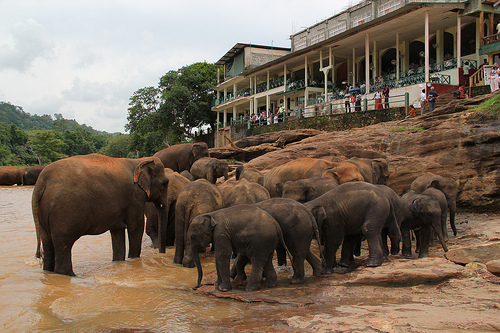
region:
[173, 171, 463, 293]
Group of baby elephants near the water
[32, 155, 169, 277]
Large elephant standing in the water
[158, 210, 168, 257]
Elephant's trunk partially submerged in water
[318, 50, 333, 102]
Y shaped column attached to roof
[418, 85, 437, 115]
People walking up the stairs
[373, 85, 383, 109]
Woman in red skirt and white top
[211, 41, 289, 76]
Flat roof on top of building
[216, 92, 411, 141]
Short metal railing above wall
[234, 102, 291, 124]
People in background watching elephants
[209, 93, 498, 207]
Steep jagged rocky background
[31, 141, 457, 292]
gathering of elephants by water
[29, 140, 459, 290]
elephants coming to bathe and drink water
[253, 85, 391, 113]
people observing elephants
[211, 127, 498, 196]
large rock wall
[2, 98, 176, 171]
lots of trees on mountain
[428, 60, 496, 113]
flight of stairs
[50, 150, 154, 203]
elephant covered in mud from bathing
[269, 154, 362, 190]
elephant coated skin in mud to stay cool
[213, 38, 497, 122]
three story building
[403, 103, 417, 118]
observer setting down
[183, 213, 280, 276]
Gray elephant standing on rock.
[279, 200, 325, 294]
Elephant standing on rock.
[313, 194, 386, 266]
Gray elephant standing on rock.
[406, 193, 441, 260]
Gray elephant standing on rock.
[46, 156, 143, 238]
Large elephant standing in water.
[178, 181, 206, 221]
Large elephant standing in water.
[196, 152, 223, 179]
Elephant standing in water.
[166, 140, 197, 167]
Elephant standing in water.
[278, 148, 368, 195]
Elephant standing in water.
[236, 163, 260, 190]
Elephant standing in rocky area near water.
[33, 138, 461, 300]
a large group of elephants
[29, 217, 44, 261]
the tail of an elephant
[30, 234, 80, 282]
the rear legs of an elephant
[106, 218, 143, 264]
the front legs of an elephant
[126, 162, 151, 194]
the ear of an elephant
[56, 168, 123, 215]
the side of an elephant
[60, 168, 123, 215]
the skin of an elephant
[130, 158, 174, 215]
the head of an elephant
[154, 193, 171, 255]
the trunk of an elephant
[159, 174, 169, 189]
the eye of an elephant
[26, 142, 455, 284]
a bunch of elephants in the water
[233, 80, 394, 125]
a crowd watching the elephants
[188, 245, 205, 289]
the trunk of an elephant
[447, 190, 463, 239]
the trunk of an elephant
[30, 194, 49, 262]
the tail of an elephant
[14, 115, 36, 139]
the leaves of the trees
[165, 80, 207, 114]
the leaves of a tree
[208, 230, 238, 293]
the front legs of an elephant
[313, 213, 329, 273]
the tail of an elephant